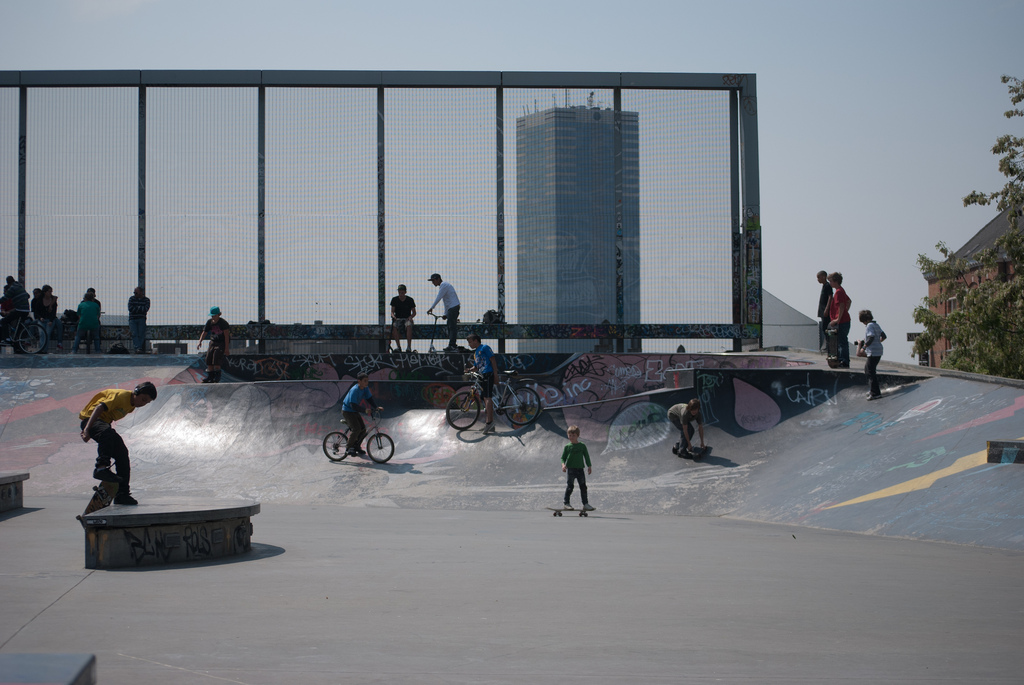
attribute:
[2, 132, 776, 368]
fence — metal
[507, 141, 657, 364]
tower — blue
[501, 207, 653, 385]
tower — tall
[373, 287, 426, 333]
shirt — black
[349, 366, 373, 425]
shirt — blue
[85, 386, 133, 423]
shirt —  YELLOW,  CHILD's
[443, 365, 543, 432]
bike —  for MOUNTAIN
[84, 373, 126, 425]
shirt — yellow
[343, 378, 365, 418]
shirt — blue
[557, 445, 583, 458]
shirt — green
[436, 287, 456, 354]
shirt — white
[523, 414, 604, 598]
boy — young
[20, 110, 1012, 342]
sky — blue